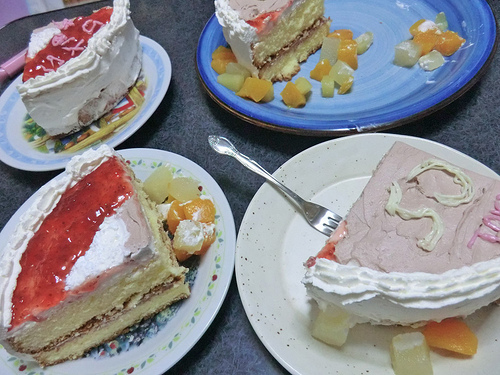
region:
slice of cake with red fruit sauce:
[3, 143, 195, 366]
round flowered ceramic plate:
[6, 145, 237, 373]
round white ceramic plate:
[236, 127, 494, 374]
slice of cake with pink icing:
[295, 138, 497, 353]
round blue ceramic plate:
[185, 3, 497, 143]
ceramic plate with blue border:
[1, 32, 174, 174]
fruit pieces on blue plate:
[202, 20, 472, 116]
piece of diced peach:
[425, 315, 482, 359]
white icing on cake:
[307, 251, 497, 323]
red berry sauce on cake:
[15, 156, 137, 332]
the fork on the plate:
[206, 133, 343, 235]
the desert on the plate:
[3, 141, 191, 366]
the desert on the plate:
[302, 139, 499, 325]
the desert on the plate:
[212, 0, 329, 85]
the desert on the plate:
[16, 0, 143, 137]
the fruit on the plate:
[208, 12, 463, 104]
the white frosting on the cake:
[302, 257, 499, 327]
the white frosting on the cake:
[0, 143, 118, 338]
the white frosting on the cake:
[19, 0, 144, 140]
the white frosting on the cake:
[213, 0, 259, 86]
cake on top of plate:
[7, 1, 173, 171]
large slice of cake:
[0, 140, 235, 373]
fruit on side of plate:
[124, 148, 231, 265]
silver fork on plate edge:
[207, 133, 342, 237]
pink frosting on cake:
[303, 143, 498, 324]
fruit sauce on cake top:
[2, 145, 143, 336]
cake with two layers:
[5, 252, 187, 363]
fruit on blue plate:
[200, 1, 495, 132]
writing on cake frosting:
[372, 143, 494, 251]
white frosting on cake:
[23, 3, 140, 135]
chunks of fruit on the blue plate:
[206, 14, 466, 108]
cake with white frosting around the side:
[26, 3, 138, 143]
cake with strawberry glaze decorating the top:
[14, 160, 131, 322]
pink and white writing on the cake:
[383, 160, 497, 255]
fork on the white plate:
[204, 128, 350, 240]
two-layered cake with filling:
[39, 253, 183, 372]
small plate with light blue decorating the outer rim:
[0, 14, 176, 181]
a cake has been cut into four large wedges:
[17, 5, 497, 362]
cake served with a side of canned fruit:
[8, 160, 229, 365]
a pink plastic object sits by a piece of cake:
[0, 44, 36, 99]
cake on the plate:
[315, 157, 495, 374]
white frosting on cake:
[325, 269, 467, 316]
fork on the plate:
[216, 132, 362, 230]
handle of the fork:
[205, 118, 310, 212]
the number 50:
[378, 155, 478, 269]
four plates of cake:
[86, 6, 496, 327]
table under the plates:
[169, 107, 206, 145]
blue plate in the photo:
[371, 10, 415, 40]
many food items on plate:
[145, 165, 215, 271]